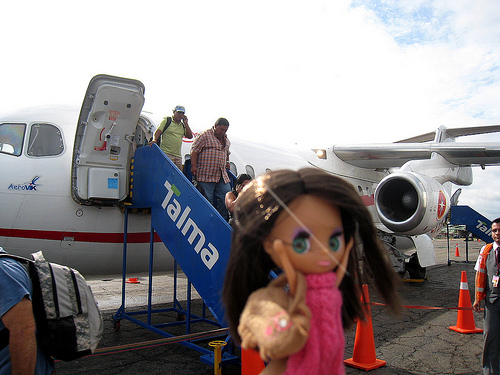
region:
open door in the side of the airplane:
[69, 70, 173, 235]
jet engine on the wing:
[357, 117, 468, 251]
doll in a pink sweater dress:
[219, 157, 396, 374]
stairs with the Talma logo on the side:
[137, 76, 307, 357]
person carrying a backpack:
[1, 229, 124, 371]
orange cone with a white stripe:
[441, 265, 484, 341]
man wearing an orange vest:
[456, 217, 499, 373]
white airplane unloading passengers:
[3, 35, 493, 372]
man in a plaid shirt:
[182, 109, 246, 213]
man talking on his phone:
[149, 80, 194, 181]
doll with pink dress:
[235, 179, 357, 365]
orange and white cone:
[450, 268, 477, 338]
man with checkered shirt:
[195, 112, 234, 197]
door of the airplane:
[77, 65, 130, 211]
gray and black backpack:
[22, 252, 109, 362]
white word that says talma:
[156, 171, 226, 276]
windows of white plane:
[4, 120, 69, 164]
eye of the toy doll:
[290, 227, 310, 256]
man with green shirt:
[162, 100, 189, 162]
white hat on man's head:
[172, 102, 188, 115]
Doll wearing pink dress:
[235, 175, 372, 365]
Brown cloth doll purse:
[234, 264, 319, 364]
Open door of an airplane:
[70, 63, 140, 231]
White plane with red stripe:
[5, 89, 475, 280]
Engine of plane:
[377, 168, 452, 233]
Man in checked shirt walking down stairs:
[192, 114, 244, 217]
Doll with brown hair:
[220, 167, 383, 373]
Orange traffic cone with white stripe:
[445, 266, 482, 352]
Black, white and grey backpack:
[23, 257, 124, 370]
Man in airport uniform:
[472, 223, 497, 366]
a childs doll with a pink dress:
[219, 165, 391, 373]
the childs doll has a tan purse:
[237, 268, 314, 360]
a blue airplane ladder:
[117, 140, 267, 362]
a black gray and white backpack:
[3, 247, 98, 362]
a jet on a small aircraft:
[375, 169, 451, 234]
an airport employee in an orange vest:
[473, 218, 498, 372]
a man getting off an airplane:
[192, 116, 237, 217]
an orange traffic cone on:
[445, 263, 480, 337]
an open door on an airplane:
[70, 75, 145, 204]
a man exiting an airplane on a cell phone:
[150, 107, 187, 177]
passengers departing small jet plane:
[0, 71, 499, 326]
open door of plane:
[71, 74, 147, 209]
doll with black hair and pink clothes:
[223, 166, 404, 373]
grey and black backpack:
[2, 248, 102, 365]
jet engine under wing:
[334, 140, 499, 237]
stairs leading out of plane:
[133, 145, 231, 321]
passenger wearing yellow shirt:
[153, 104, 193, 167]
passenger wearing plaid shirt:
[188, 116, 232, 207]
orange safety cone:
[451, 271, 481, 336]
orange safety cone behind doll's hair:
[346, 284, 388, 371]